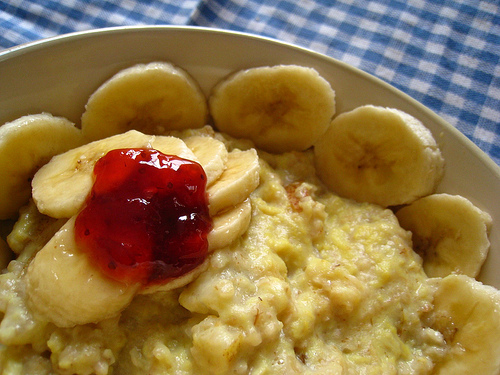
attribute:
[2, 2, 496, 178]
tablecloth — checkered, white, blue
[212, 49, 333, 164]
banana — slice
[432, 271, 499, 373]
banana — slice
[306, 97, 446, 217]
banana — slice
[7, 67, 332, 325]
bananas — sliced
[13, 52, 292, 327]
bananas — stack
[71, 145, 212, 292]
jelly — strawberry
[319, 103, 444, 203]
banana slice — round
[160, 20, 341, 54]
bowl — white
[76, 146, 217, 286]
jelly — strawberry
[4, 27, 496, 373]
bowl — white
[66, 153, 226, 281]
jam — strawberry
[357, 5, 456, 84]
tablecloth — white, blue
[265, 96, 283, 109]
seed — dark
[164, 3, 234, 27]
tablecloth — wrinkled